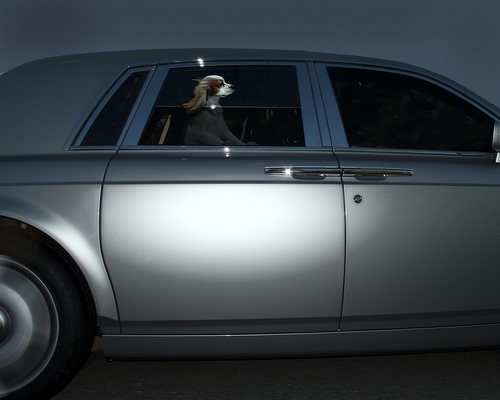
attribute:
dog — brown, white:
[177, 69, 248, 154]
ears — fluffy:
[182, 83, 220, 115]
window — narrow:
[322, 62, 415, 152]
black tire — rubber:
[0, 222, 95, 398]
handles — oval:
[263, 163, 417, 187]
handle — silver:
[356, 171, 387, 181]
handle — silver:
[284, 163, 393, 187]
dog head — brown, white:
[193, 67, 240, 106]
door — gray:
[313, 60, 499, 332]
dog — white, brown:
[183, 72, 254, 147]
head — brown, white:
[191, 71, 236, 103]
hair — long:
[181, 78, 208, 113]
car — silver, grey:
[3, 39, 490, 384]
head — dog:
[199, 74, 234, 96]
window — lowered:
[117, 61, 335, 170]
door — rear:
[101, 154, 345, 333]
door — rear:
[93, 50, 352, 330]